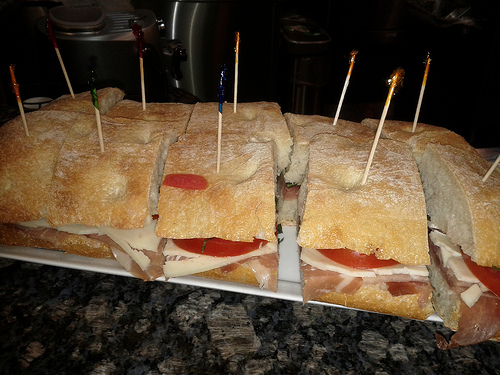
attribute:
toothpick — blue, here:
[208, 56, 237, 176]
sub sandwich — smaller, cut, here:
[156, 114, 285, 305]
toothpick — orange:
[358, 66, 405, 196]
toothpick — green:
[82, 49, 114, 164]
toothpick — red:
[128, 16, 156, 118]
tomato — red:
[176, 237, 273, 260]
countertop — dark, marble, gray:
[18, 264, 457, 373]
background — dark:
[13, 6, 494, 113]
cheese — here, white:
[170, 243, 275, 278]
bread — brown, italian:
[157, 128, 281, 244]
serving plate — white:
[5, 228, 497, 341]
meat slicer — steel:
[35, 13, 169, 65]